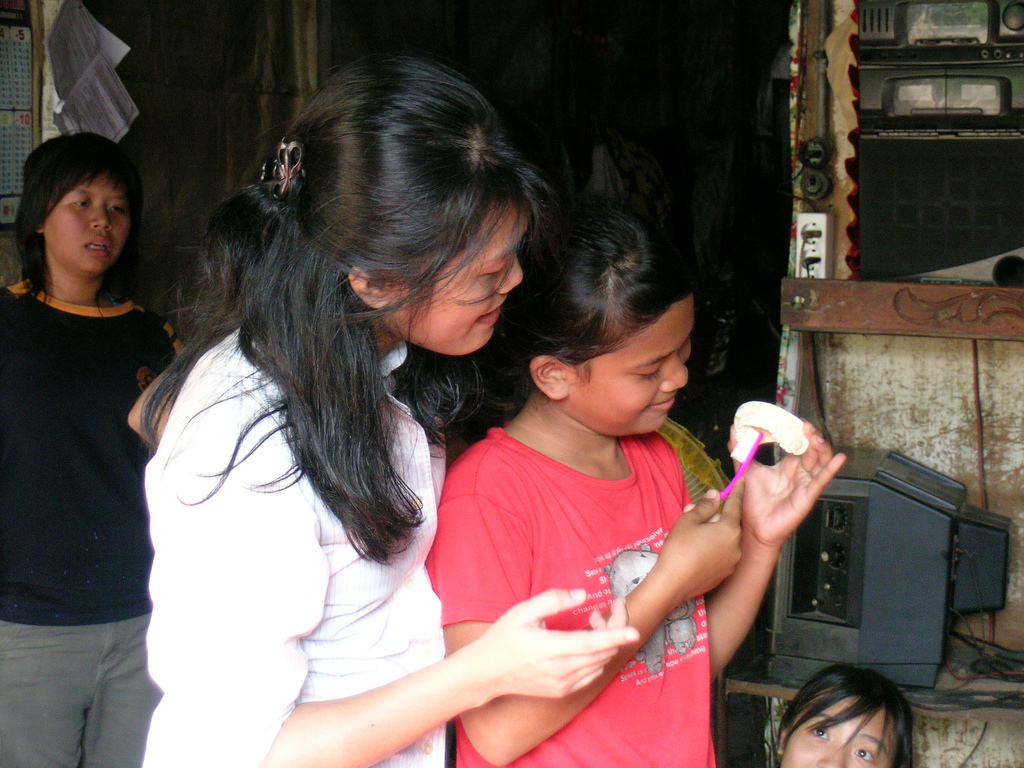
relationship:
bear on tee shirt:
[603, 542, 698, 675] [427, 424, 720, 764]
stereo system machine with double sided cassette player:
[857, 0, 1024, 288] [724, 215, 893, 453]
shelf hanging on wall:
[788, 274, 1015, 346] [808, 254, 1020, 542]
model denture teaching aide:
[719, 378, 806, 485] [611, 434, 888, 748]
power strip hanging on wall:
[761, 134, 863, 318] [747, 42, 989, 559]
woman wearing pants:
[5, 130, 192, 764] [2, 595, 193, 756]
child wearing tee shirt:
[417, 193, 850, 764] [427, 424, 720, 764]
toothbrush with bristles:
[711, 418, 768, 503] [730, 418, 767, 470]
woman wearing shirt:
[4, 124, 227, 764] [2, 279, 184, 627]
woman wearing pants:
[4, 124, 227, 764] [4, 618, 165, 765]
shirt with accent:
[2, 282, 199, 639] [130, 363, 157, 398]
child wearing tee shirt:
[425, 206, 850, 764] [427, 424, 720, 764]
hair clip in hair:
[212, 119, 323, 219] [223, 50, 569, 565]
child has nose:
[425, 206, 850, 764] [652, 358, 707, 406]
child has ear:
[425, 206, 850, 764] [521, 341, 578, 409]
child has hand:
[425, 206, 850, 764] [659, 482, 757, 603]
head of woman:
[216, 46, 552, 381] [103, 39, 644, 763]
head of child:
[520, 195, 706, 461] [425, 206, 850, 764]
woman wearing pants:
[5, 130, 192, 764] [4, 618, 165, 765]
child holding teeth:
[417, 193, 850, 764] [732, 394, 813, 468]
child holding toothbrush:
[417, 193, 850, 764] [706, 420, 767, 503]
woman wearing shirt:
[103, 39, 644, 763] [131, 325, 464, 764]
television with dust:
[760, 446, 990, 699] [784, 623, 865, 660]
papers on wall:
[39, 5, 150, 150] [2, 1, 567, 397]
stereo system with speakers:
[857, 0, 1024, 288] [840, 135, 990, 274]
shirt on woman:
[131, 325, 464, 764] [103, 39, 644, 763]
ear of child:
[520, 348, 577, 409] [417, 193, 850, 764]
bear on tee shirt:
[590, 536, 705, 679] [427, 424, 720, 764]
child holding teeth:
[425, 206, 850, 764] [719, 396, 815, 464]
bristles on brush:
[730, 428, 759, 459] [710, 420, 773, 503]